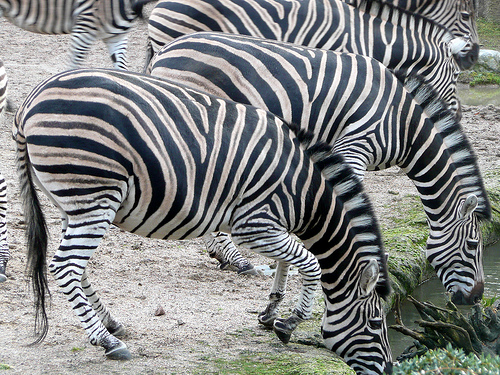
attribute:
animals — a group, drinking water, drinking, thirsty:
[2, 2, 498, 374]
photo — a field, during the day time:
[5, 4, 500, 374]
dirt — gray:
[0, 0, 312, 373]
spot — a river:
[382, 203, 498, 359]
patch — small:
[384, 338, 497, 374]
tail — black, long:
[9, 117, 54, 346]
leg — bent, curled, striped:
[45, 171, 137, 347]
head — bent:
[313, 247, 400, 374]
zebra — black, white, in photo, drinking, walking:
[0, 68, 406, 370]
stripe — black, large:
[14, 103, 173, 236]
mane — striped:
[274, 122, 396, 290]